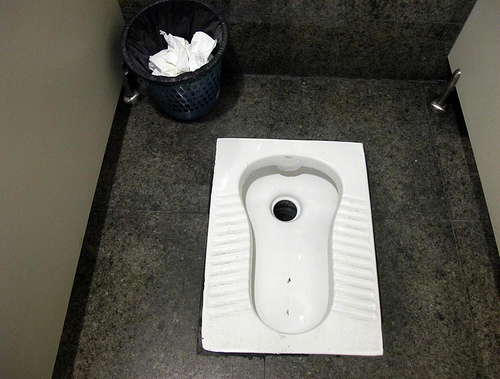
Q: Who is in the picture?
A: No one.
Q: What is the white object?
A: The urinal.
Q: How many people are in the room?
A: None.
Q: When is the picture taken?
A: When the room is empty.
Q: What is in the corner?
A: A trash can.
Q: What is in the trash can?
A: White paper.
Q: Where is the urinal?
A: In the middle of the floor.